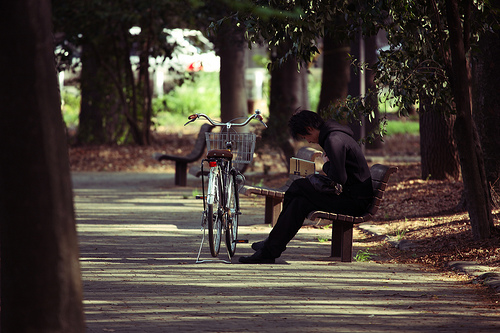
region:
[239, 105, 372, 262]
person sitting on park bench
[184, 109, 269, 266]
silver bicycle in front of person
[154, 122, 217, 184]
brown bench in park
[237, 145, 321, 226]
brown bench in park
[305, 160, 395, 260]
brown bench in park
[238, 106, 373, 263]
man wearing black pants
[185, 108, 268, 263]
The bike parked in front of the bench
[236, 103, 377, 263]
The man sitting on a park bench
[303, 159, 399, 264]
The bench that the man is sitting on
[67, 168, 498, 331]
The pathway in front of the benches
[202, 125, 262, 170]
The basket connected to the bike's handlebars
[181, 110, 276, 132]
The handlebars of the bike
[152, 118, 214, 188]
The furthest bench from the man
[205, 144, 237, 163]
The brown seat of the bicycle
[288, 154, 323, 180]
The book that the man is reading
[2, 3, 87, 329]
tall brown tree trunck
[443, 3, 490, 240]
tall brown tree trunck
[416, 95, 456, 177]
tall brown tree trunck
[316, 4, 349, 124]
tall brown tree trunck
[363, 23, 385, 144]
tall brown tree trunck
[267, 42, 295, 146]
tall brown tree trunck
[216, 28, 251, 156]
tall brown tree trunck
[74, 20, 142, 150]
tall brown tree trunck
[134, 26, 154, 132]
tall brown tree trunck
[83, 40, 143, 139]
tall brown tree trunck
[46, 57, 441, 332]
person sitting on bench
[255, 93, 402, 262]
man sitting on the bench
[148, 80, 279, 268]
a 10 speed bike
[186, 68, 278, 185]
a wire basket on a bike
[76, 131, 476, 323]
a pathway through a park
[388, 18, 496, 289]
trees lining a walkway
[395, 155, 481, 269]
dead leaves on ground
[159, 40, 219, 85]
people standing in the disance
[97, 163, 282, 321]
tree shadows on the ground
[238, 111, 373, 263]
man sitting on a bench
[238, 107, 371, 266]
man sitting in the park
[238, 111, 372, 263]
man wearing a dark brown shirt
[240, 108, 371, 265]
man wearing a pair of black pants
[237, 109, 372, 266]
guy sitting on a bench reading a book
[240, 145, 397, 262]
brown bench in the park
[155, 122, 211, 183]
park bench in the distance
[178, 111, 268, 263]
bicycle parked in front of the man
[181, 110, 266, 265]
silver and black bicycle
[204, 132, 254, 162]
silver basket on the bicycle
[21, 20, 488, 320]
bicyclist seated in park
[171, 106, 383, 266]
bicycle in front of seated person on bench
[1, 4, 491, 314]
thick trunks and hanging branches in shade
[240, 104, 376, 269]
head bent forward above knees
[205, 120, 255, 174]
a metal basket attached to front of bicycle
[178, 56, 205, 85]
red flower growing against a white fence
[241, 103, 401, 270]
man sits on a bench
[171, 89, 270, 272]
teh bike is park on the walkway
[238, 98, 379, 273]
man wears black clothes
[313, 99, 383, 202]
the sweatshirt has a hood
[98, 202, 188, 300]
sun light is cast on the ground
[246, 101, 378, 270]
the man is bend forward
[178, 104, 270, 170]
a basket on front a bike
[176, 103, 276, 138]
the handles of a bike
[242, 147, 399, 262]
the chair is made of wood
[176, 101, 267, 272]
bike is on the ground